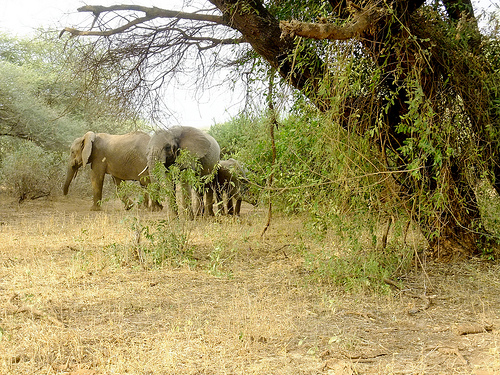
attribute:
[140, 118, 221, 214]
elephant — gray, largest, eating, male, grey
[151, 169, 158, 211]
trunk — long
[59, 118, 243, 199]
elephants — gray, walking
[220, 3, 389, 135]
branch — hanging, brown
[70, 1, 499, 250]
tree — shady, large, brown, tall, wiry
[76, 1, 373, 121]
branches — hanging, dry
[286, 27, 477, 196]
leaves — green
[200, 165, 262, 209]
elephant — small, the baby, youngest, grey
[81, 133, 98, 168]
ear — large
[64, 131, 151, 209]
elephant — gray, large, female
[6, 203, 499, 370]
grass — dry, brown, dead, tall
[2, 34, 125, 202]
tree — green, large, willow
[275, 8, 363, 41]
branch — broken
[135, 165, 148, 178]
tusk — ivory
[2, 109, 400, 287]
shrubs — leafy, green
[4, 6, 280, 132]
sky — gray, hazy